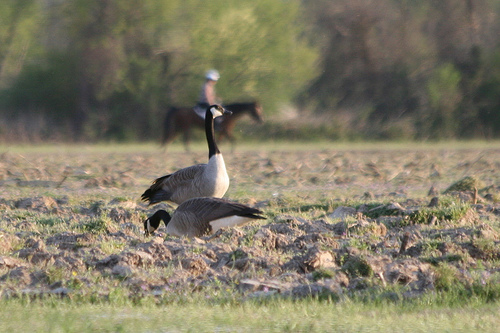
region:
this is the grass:
[369, 303, 487, 327]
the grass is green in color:
[223, 299, 332, 331]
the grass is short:
[221, 297, 336, 330]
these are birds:
[141, 97, 258, 232]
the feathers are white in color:
[180, 172, 226, 192]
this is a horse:
[168, 99, 254, 136]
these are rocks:
[277, 262, 314, 287]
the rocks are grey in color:
[276, 244, 313, 268]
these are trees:
[131, 103, 158, 118]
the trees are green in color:
[63, 86, 143, 125]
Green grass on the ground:
[248, 301, 365, 329]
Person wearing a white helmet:
[204, 65, 224, 82]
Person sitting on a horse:
[200, 67, 227, 118]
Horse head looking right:
[239, 93, 270, 124]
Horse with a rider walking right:
[160, 67, 277, 152]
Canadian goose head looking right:
[205, 103, 238, 123]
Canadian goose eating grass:
[138, 210, 165, 242]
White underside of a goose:
[205, 212, 257, 231]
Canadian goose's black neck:
[200, 117, 222, 157]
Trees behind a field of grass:
[7, 7, 492, 99]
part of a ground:
[413, 191, 483, 229]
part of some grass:
[364, 305, 394, 330]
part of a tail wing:
[218, 188, 258, 223]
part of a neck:
[210, 145, 235, 177]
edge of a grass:
[318, 285, 373, 306]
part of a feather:
[176, 173, 196, 194]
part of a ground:
[318, 150, 388, 205]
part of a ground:
[396, 210, 441, 234]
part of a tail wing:
[236, 205, 271, 244]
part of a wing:
[176, 192, 211, 228]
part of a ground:
[329, 215, 381, 265]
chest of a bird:
[200, 155, 237, 199]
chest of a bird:
[209, 161, 234, 191]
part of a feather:
[170, 167, 200, 197]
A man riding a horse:
[154, 75, 277, 144]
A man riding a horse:
[125, 61, 335, 126]